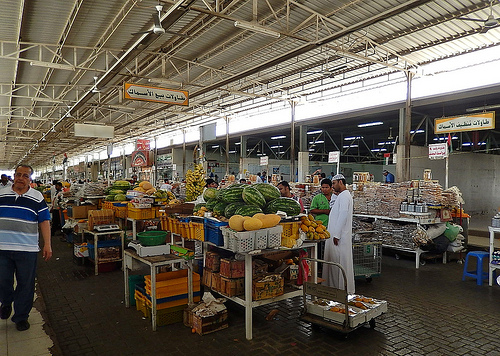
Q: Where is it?
A: This is at the market.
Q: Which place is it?
A: It is a market.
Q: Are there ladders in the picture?
A: No, there are no ladders.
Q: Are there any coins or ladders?
A: No, there are no ladders or coins.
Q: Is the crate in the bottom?
A: Yes, the crate is in the bottom of the image.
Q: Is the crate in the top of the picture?
A: No, the crate is in the bottom of the image.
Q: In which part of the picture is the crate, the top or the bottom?
A: The crate is in the bottom of the image.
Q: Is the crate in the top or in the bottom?
A: The crate is in the bottom of the image.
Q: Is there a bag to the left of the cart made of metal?
A: No, there is a crate to the left of the cart.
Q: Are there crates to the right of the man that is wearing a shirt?
A: Yes, there is a crate to the right of the man.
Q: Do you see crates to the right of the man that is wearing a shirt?
A: Yes, there is a crate to the right of the man.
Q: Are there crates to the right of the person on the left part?
A: Yes, there is a crate to the right of the man.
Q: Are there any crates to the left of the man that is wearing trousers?
A: No, the crate is to the right of the man.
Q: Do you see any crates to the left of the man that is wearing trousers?
A: No, the crate is to the right of the man.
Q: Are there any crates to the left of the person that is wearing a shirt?
A: No, the crate is to the right of the man.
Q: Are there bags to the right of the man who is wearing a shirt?
A: No, there is a crate to the right of the man.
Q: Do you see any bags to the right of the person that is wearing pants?
A: No, there is a crate to the right of the man.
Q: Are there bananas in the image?
A: Yes, there are bananas.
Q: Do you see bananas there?
A: Yes, there are bananas.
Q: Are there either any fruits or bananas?
A: Yes, there are bananas.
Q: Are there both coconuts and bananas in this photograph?
A: No, there are bananas but no coconuts.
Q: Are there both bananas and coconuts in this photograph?
A: No, there are bananas but no coconuts.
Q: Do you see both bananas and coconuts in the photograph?
A: No, there are bananas but no coconuts.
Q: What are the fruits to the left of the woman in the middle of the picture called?
A: The fruits are bananas.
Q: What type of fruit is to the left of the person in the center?
A: The fruits are bananas.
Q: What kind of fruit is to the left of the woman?
A: The fruits are bananas.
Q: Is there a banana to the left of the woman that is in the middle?
A: Yes, there are bananas to the left of the woman.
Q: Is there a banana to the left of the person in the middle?
A: Yes, there are bananas to the left of the woman.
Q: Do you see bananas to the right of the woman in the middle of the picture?
A: No, the bananas are to the left of the woman.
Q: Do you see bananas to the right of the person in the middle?
A: No, the bananas are to the left of the woman.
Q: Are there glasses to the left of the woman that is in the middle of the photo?
A: No, there are bananas to the left of the woman.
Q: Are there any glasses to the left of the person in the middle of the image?
A: No, there are bananas to the left of the woman.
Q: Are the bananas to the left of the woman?
A: Yes, the bananas are to the left of the woman.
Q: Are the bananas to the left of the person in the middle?
A: Yes, the bananas are to the left of the woman.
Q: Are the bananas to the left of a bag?
A: No, the bananas are to the left of the woman.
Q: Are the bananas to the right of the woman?
A: No, the bananas are to the left of the woman.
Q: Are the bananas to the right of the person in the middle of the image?
A: No, the bananas are to the left of the woman.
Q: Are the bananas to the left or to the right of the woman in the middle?
A: The bananas are to the left of the woman.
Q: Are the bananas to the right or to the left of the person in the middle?
A: The bananas are to the left of the woman.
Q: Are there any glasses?
A: No, there are no glasses.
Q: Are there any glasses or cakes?
A: No, there are no glasses or cakes.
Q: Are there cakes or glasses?
A: No, there are no glasses or cakes.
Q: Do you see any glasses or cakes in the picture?
A: No, there are no glasses or cakes.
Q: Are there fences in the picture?
A: No, there are no fences.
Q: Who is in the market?
A: The people are in the market.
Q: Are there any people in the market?
A: Yes, there are people in the market.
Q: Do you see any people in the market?
A: Yes, there are people in the market.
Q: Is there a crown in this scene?
A: No, there are no crowns.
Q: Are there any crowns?
A: No, there are no crowns.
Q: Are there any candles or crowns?
A: No, there are no crowns or candles.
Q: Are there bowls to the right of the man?
A: Yes, there is a bowl to the right of the man.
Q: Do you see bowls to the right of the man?
A: Yes, there is a bowl to the right of the man.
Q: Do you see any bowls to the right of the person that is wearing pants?
A: Yes, there is a bowl to the right of the man.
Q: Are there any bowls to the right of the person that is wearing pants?
A: Yes, there is a bowl to the right of the man.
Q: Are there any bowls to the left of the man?
A: No, the bowl is to the right of the man.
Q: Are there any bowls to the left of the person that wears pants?
A: No, the bowl is to the right of the man.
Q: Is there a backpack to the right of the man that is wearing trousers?
A: No, there is a bowl to the right of the man.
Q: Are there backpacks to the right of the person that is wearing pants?
A: No, there is a bowl to the right of the man.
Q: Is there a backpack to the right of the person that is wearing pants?
A: No, there is a bowl to the right of the man.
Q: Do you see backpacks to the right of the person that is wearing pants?
A: No, there is a bowl to the right of the man.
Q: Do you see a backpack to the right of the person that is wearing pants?
A: No, there is a bowl to the right of the man.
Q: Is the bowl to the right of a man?
A: Yes, the bowl is to the right of a man.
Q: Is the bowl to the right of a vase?
A: No, the bowl is to the right of a man.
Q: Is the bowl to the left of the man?
A: No, the bowl is to the right of the man.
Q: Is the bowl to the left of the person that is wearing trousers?
A: No, the bowl is to the right of the man.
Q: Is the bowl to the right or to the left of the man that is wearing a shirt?
A: The bowl is to the right of the man.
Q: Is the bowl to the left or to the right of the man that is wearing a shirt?
A: The bowl is to the right of the man.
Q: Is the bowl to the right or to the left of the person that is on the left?
A: The bowl is to the right of the man.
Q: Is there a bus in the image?
A: No, there are no buses.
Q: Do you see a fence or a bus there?
A: No, there are no buses or fences.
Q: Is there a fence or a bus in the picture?
A: No, there are no buses or fences.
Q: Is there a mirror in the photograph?
A: No, there are no mirrors.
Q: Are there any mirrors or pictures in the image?
A: No, there are no mirrors or pictures.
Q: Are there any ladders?
A: No, there are no ladders.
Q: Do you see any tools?
A: No, there are no tools.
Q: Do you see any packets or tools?
A: No, there are no tools or packets.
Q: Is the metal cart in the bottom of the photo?
A: Yes, the cart is in the bottom of the image.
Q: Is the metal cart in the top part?
A: No, the cart is in the bottom of the image.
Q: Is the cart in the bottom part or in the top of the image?
A: The cart is in the bottom of the image.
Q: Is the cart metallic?
A: Yes, the cart is metallic.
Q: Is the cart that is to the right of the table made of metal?
A: Yes, the cart is made of metal.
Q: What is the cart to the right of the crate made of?
A: The cart is made of metal.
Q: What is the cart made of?
A: The cart is made of metal.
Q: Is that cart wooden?
A: No, the cart is metallic.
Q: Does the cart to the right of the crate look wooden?
A: No, the cart is metallic.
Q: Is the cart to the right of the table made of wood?
A: No, the cart is made of metal.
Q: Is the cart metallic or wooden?
A: The cart is metallic.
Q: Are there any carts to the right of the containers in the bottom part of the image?
A: Yes, there is a cart to the right of the containers.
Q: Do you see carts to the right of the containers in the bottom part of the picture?
A: Yes, there is a cart to the right of the containers.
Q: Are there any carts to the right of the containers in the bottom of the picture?
A: Yes, there is a cart to the right of the containers.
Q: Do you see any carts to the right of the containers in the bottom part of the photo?
A: Yes, there is a cart to the right of the containers.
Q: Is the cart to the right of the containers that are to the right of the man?
A: Yes, the cart is to the right of the containers.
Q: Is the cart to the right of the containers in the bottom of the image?
A: Yes, the cart is to the right of the containers.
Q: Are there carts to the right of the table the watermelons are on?
A: Yes, there is a cart to the right of the table.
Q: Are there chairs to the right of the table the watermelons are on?
A: No, there is a cart to the right of the table.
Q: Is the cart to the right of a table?
A: Yes, the cart is to the right of a table.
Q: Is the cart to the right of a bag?
A: No, the cart is to the right of a table.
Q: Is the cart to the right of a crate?
A: Yes, the cart is to the right of a crate.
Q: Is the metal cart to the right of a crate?
A: Yes, the cart is to the right of a crate.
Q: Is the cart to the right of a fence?
A: No, the cart is to the right of a crate.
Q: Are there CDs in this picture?
A: No, there are no cds.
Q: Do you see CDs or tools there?
A: No, there are no CDs or tools.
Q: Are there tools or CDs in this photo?
A: No, there are no CDs or tools.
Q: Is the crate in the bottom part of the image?
A: Yes, the crate is in the bottom of the image.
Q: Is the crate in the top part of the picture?
A: No, the crate is in the bottom of the image.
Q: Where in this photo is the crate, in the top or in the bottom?
A: The crate is in the bottom of the image.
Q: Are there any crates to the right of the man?
A: Yes, there is a crate to the right of the man.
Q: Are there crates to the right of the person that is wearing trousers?
A: Yes, there is a crate to the right of the man.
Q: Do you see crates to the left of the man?
A: No, the crate is to the right of the man.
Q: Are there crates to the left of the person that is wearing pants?
A: No, the crate is to the right of the man.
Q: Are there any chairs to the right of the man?
A: No, there is a crate to the right of the man.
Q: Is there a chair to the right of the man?
A: No, there is a crate to the right of the man.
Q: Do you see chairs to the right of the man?
A: No, there is a crate to the right of the man.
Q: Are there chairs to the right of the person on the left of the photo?
A: No, there is a crate to the right of the man.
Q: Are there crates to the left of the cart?
A: Yes, there is a crate to the left of the cart.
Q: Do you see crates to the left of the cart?
A: Yes, there is a crate to the left of the cart.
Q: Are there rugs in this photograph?
A: No, there are no rugs.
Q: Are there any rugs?
A: No, there are no rugs.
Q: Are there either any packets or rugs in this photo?
A: No, there are no rugs or packets.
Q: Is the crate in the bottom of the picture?
A: Yes, the crate is in the bottom of the image.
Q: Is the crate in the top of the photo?
A: No, the crate is in the bottom of the image.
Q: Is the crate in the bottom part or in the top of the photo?
A: The crate is in the bottom of the image.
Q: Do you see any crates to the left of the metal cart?
A: Yes, there is a crate to the left of the cart.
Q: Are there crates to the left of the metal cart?
A: Yes, there is a crate to the left of the cart.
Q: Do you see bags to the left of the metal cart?
A: No, there is a crate to the left of the cart.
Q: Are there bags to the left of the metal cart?
A: No, there is a crate to the left of the cart.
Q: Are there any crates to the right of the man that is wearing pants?
A: Yes, there is a crate to the right of the man.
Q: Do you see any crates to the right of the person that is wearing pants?
A: Yes, there is a crate to the right of the man.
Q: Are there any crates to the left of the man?
A: No, the crate is to the right of the man.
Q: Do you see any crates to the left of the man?
A: No, the crate is to the right of the man.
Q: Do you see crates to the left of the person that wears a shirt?
A: No, the crate is to the right of the man.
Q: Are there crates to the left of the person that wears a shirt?
A: No, the crate is to the right of the man.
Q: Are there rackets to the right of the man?
A: No, there is a crate to the right of the man.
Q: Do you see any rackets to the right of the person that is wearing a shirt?
A: No, there is a crate to the right of the man.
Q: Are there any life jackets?
A: No, there are no life jackets.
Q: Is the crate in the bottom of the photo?
A: Yes, the crate is in the bottom of the image.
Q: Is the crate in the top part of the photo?
A: No, the crate is in the bottom of the image.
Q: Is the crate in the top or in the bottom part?
A: The crate is in the bottom of the image.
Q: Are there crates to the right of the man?
A: Yes, there is a crate to the right of the man.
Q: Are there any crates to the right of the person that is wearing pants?
A: Yes, there is a crate to the right of the man.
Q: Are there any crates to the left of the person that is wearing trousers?
A: No, the crate is to the right of the man.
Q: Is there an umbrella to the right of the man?
A: No, there is a crate to the right of the man.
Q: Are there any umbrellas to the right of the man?
A: No, there is a crate to the right of the man.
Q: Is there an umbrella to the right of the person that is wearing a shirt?
A: No, there is a crate to the right of the man.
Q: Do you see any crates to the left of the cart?
A: Yes, there is a crate to the left of the cart.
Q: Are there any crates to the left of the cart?
A: Yes, there is a crate to the left of the cart.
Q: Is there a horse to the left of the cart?
A: No, there is a crate to the left of the cart.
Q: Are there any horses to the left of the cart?
A: No, there is a crate to the left of the cart.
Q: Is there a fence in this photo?
A: No, there are no fences.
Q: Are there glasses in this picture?
A: No, there are no glasses.